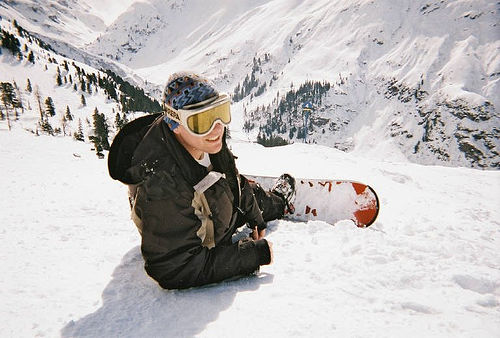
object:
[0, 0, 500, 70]
mountain.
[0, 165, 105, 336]
snow.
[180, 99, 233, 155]
face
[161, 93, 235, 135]
goggles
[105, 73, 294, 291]
man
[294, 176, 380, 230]
snowboard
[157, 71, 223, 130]
hat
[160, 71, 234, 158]
head.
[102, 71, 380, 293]
snowboarder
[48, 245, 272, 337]
shadow.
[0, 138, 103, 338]
ground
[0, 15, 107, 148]
trees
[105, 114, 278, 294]
jacket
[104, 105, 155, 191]
hood.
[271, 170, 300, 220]
boot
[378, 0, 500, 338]
snow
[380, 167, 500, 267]
footprints.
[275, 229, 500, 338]
footprints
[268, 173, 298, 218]
foot.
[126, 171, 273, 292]
sleeve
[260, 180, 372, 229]
snow.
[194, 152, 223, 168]
shirt